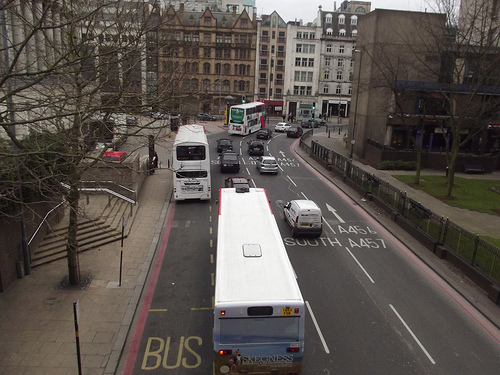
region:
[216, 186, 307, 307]
White roof of bus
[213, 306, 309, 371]
Back of blue and white bus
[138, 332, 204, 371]
The word "BUS" in yellow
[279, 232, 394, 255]
Street name on road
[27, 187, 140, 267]
Steps in front of building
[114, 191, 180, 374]
Red strip down side of street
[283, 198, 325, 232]
Van going down the street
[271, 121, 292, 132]
White car going down the street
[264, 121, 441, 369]
White lane seperators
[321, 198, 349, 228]
White directional arrow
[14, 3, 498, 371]
a street scene viewed from above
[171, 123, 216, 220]
a two-story white bus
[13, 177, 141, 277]
shallow steps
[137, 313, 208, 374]
yellow text on street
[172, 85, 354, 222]
road curves to the right in the distance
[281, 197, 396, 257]
white numbers and letters on road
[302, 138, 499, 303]
fence beside the road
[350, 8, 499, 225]
patch of grass in front of building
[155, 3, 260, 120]
brown building with gables on the roof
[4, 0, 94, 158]
pillars in front of building seen through tree branches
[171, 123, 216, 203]
A double decker bus.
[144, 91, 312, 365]
Three buses on the street.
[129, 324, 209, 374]
The street has bus written on it.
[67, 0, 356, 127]
Buildings are in the background.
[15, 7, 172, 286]
The trees have no leaves.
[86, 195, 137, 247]
A set of steps.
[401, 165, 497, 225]
A patch of grass.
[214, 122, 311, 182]
Cars are on the road.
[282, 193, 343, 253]
A white van.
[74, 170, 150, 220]
A handrail.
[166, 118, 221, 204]
the bus is white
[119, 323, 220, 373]
the word bus is written on the street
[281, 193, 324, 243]
the truck is white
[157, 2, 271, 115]
the building is multi-story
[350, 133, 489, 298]
the fence is along the street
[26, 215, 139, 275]
the steps lead into the building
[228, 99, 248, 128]
the back of the bus is green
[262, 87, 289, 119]
the front of the building is red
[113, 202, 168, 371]
a red stripe runs along the curb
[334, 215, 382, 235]
A456 is written on the street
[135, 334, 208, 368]
the word bus on the road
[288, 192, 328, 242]
a white van driving on road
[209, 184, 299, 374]
a top of a white bus on road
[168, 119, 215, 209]
a white double decker bus on parking area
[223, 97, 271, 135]
a double decker bus riding down the street with red on it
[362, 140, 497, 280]
a brown fence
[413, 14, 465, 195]
two bear trees next to sidewalk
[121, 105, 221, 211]
a person is waiting to catch the bus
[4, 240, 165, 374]
a cobble stone sidewalk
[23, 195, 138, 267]
stairways to a building